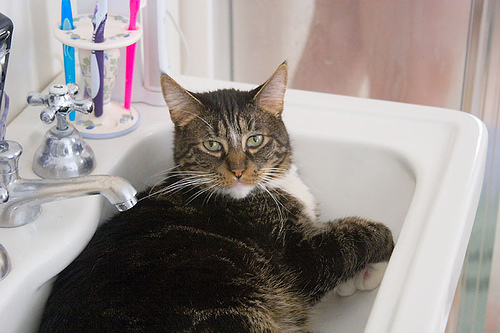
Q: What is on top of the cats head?
A: Pointy ears.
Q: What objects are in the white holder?
A: Toothbrushes.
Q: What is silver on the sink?
A: Faucet.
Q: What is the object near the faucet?
A: Faucet knob.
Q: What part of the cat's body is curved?
A: Paws.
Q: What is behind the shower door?
A: Human legs.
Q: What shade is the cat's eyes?
A: Green.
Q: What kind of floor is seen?
A: Tiled.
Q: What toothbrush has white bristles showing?
A: Pink toothbrush.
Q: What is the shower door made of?
A: Glass.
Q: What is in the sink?
A: Cat.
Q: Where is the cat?
A: Sink.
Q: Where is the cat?
A: Sink.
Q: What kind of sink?
A: Ceramic.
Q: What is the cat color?
A: Brown.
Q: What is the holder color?
A: White.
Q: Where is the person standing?
A: Shower.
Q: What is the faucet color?
A: Silver.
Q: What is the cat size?
A: Large.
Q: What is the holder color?
A: White.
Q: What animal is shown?
A: A cat.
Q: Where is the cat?
A: In the sink.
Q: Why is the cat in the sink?
A: Resting.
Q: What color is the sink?
A: White.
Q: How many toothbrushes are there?
A: Three.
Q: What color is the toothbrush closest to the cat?
A: Pink.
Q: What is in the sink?
A: A cat.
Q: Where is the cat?
A: In the sink.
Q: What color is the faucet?
A: Silver.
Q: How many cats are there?
A: One.